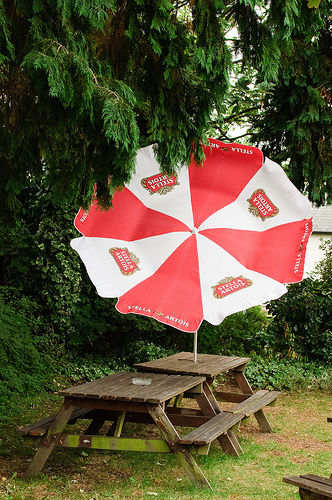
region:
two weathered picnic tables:
[11, 349, 279, 477]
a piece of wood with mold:
[59, 430, 170, 452]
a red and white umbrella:
[70, 136, 313, 335]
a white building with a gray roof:
[303, 180, 329, 281]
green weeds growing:
[69, 340, 326, 388]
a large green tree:
[0, 0, 331, 211]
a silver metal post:
[192, 329, 198, 362]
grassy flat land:
[2, 390, 327, 498]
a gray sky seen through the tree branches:
[207, 90, 290, 167]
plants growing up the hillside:
[10, 174, 164, 344]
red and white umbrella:
[87, 165, 291, 323]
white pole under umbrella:
[185, 311, 205, 364]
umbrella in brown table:
[95, 139, 285, 443]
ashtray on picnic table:
[129, 369, 157, 390]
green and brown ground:
[263, 421, 330, 481]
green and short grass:
[205, 432, 325, 483]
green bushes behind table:
[225, 253, 324, 376]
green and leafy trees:
[12, 0, 239, 196]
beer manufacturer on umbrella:
[102, 127, 299, 322]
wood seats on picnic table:
[178, 391, 284, 461]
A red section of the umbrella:
[136, 231, 201, 334]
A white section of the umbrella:
[193, 227, 266, 322]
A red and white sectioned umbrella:
[78, 153, 309, 330]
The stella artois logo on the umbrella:
[209, 274, 251, 297]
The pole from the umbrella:
[177, 314, 201, 364]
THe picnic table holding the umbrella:
[140, 353, 274, 419]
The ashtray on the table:
[126, 376, 151, 384]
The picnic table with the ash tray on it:
[29, 351, 216, 491]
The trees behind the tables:
[12, 129, 311, 378]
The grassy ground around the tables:
[24, 393, 329, 494]